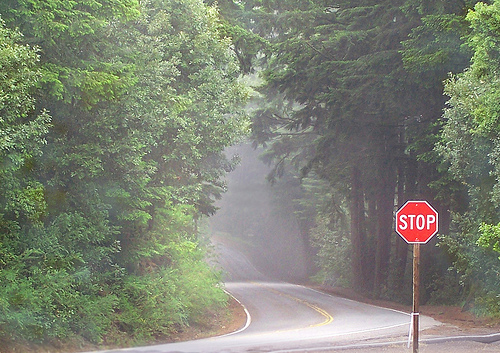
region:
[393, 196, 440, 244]
a red and white stop sign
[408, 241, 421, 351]
a brown wooden pole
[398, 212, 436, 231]
white letters on the red sign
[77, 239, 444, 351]
a gray paved road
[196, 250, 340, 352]
a yellow stripe in the road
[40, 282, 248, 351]
dirt on the side of the road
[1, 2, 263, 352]
green trees on the side of the road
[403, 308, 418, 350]
a white ribbon on the pole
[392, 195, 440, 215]
the top of the stop sign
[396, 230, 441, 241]
the bottom of the stop sign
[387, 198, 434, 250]
part of a red road sign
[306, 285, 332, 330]
two lines on the road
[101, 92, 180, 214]
part of some green leaves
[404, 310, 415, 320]
part of a tied rope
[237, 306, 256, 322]
edge of the road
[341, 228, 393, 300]
stems of some trees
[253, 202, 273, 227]
part of some mist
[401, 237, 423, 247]
edge of the road sign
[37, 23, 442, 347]
windy empty road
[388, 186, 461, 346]
red and white stop sign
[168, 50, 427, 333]
street lined with tall trees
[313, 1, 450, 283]
tall green leafy trees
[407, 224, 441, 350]
wooden pole used to hold stop sign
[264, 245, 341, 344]
two yellow lines in center of road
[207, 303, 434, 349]
sun light shining on road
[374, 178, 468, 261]
stop sign with an octagon shape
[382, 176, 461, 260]
white letters on a red sign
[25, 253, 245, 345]
small green bushes along roadside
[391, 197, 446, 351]
A stop sign in the road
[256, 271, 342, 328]
Yellow painted lines in the road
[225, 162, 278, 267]
A foggy area up the road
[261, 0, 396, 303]
Pine trees on the edge of the road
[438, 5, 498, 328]
A tall tree with green leaves on the edge of the road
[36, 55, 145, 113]
Dark green leaves on a tree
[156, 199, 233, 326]
Light shining on the bottom of the tree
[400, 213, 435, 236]
STOP written in white letters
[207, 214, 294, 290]
The road going upward in the fog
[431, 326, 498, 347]
A white painted line in the road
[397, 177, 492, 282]
Red stop sign on pole.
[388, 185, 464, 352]
Stop sign on the road.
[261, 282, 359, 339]
Yellow line on the road.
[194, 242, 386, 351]
Road through a forest.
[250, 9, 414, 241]
Green leaves on trees.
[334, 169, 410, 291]
Brown trunk of the tree.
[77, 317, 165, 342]
Brown dirt under bushes.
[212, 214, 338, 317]
Raised road leading into forest.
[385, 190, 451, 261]
White STOP letters on sign.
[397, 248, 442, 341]
Wood pole under stop sign.